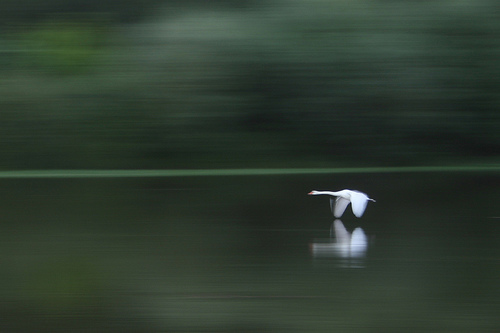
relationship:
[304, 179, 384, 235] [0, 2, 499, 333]
bird above water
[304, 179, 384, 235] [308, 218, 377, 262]
bird has reflection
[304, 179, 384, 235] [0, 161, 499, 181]
bird below line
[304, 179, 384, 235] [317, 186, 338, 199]
bird has neck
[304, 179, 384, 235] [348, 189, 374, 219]
bird has wing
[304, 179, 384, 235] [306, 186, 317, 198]
bird has head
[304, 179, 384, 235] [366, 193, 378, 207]
bird has tail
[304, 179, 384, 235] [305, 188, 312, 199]
bird has beak